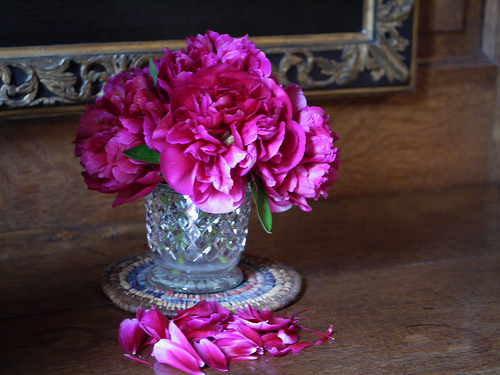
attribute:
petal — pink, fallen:
[118, 318, 143, 357]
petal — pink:
[192, 338, 228, 371]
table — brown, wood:
[1, 66, 500, 374]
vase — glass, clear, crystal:
[145, 180, 250, 293]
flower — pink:
[265, 105, 341, 213]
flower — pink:
[172, 63, 260, 131]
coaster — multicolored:
[102, 246, 302, 317]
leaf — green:
[122, 143, 162, 165]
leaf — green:
[250, 172, 272, 234]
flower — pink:
[157, 29, 272, 94]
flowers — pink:
[73, 29, 343, 213]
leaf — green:
[149, 54, 159, 86]